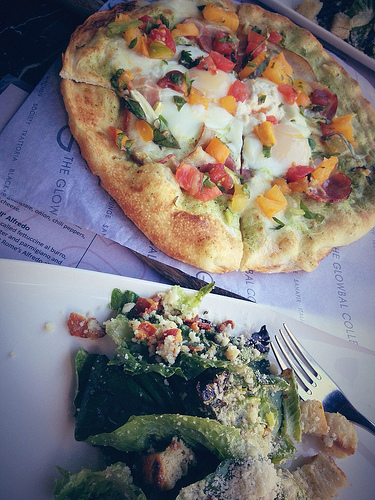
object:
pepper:
[256, 183, 290, 222]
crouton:
[292, 453, 349, 499]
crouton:
[142, 436, 194, 492]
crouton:
[300, 398, 357, 457]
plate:
[0, 257, 375, 500]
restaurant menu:
[0, 197, 73, 264]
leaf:
[69, 360, 305, 454]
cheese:
[133, 315, 183, 363]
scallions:
[299, 196, 326, 224]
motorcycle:
[266, 320, 362, 415]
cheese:
[148, 86, 285, 165]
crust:
[60, 78, 243, 273]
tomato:
[174, 161, 222, 204]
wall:
[149, 98, 179, 113]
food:
[57, 0, 375, 277]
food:
[50, 270, 358, 500]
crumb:
[45, 322, 54, 330]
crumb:
[96, 303, 102, 309]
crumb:
[7, 349, 16, 356]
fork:
[269, 323, 374, 438]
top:
[259, 320, 325, 390]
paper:
[0, 48, 375, 354]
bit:
[275, 187, 288, 204]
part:
[175, 162, 222, 203]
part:
[20, 354, 63, 439]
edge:
[130, 414, 226, 429]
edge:
[123, 361, 184, 381]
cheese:
[222, 387, 282, 490]